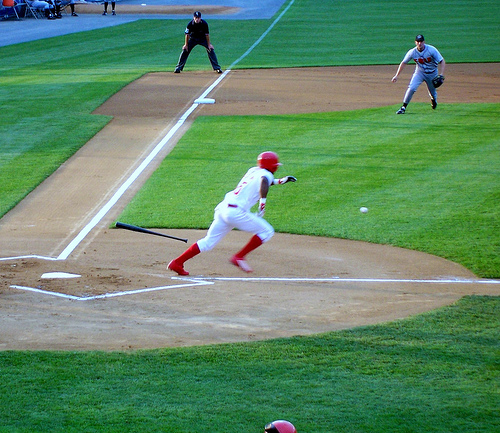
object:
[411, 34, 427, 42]
hat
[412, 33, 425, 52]
head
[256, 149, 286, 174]
helmet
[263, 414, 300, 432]
helmet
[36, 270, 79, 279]
base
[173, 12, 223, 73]
umpire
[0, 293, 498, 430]
grass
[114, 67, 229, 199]
lines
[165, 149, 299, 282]
baseball player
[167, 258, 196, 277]
shoes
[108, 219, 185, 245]
baseball bat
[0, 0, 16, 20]
spectator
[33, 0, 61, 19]
spectator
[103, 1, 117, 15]
spectator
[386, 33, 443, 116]
guy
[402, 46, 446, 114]
uniform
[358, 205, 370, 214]
baseball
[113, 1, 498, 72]
grass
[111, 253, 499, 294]
base path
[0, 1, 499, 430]
baseball field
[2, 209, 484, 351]
section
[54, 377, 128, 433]
patch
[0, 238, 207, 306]
middle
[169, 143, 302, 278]
run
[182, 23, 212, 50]
shirt